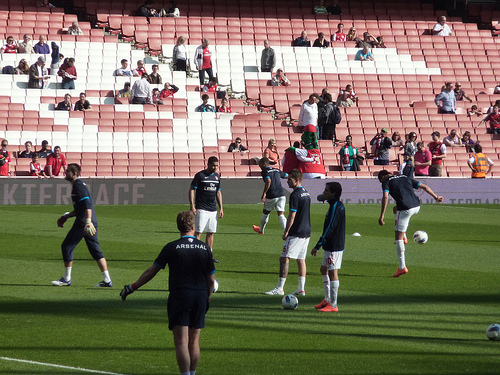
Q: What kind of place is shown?
A: It is a field.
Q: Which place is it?
A: It is a field.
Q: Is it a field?
A: Yes, it is a field.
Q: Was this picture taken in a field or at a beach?
A: It was taken at a field.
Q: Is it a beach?
A: No, it is a field.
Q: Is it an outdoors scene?
A: Yes, it is outdoors.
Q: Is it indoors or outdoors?
A: It is outdoors.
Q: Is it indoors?
A: No, it is outdoors.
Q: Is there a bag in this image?
A: No, there are no bags.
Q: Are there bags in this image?
A: No, there are no bags.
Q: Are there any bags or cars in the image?
A: No, there are no bags or cars.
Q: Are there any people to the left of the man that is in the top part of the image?
A: Yes, there is a person to the left of the man.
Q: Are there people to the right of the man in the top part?
A: No, the person is to the left of the man.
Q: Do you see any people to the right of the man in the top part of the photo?
A: No, the person is to the left of the man.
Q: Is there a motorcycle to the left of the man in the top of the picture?
A: No, there is a person to the left of the man.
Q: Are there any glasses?
A: No, there are no glasses.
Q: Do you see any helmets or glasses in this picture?
A: No, there are no glasses or helmets.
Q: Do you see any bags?
A: No, there are no bags.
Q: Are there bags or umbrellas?
A: No, there are no bags or umbrellas.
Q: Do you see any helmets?
A: No, there are no helmets.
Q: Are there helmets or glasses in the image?
A: No, there are no helmets or glasses.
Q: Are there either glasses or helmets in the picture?
A: No, there are no helmets or glasses.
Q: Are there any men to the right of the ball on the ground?
A: Yes, there is a man to the right of the ball.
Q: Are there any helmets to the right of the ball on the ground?
A: No, there is a man to the right of the ball.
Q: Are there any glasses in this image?
A: No, there are no glasses.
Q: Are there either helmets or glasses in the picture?
A: No, there are no glasses or helmets.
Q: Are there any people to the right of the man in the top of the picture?
A: No, the person is to the left of the man.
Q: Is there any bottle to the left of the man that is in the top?
A: No, there is a person to the left of the man.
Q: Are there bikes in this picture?
A: No, there are no bikes.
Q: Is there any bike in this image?
A: No, there are no bikes.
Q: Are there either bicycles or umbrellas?
A: No, there are no bicycles or umbrellas.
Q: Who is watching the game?
A: The crowd is watching the game.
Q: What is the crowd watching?
A: The crowd is watching the game.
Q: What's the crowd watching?
A: The crowd is watching the game.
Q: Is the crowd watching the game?
A: Yes, the crowd is watching the game.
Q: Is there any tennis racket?
A: No, there are no rackets.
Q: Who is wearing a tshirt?
A: The man is wearing a tshirt.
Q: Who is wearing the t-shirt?
A: The man is wearing a tshirt.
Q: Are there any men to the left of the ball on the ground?
A: Yes, there is a man to the left of the ball.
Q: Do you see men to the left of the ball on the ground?
A: Yes, there is a man to the left of the ball.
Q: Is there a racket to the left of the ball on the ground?
A: No, there is a man to the left of the ball.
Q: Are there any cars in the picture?
A: No, there are no cars.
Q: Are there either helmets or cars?
A: No, there are no cars or helmets.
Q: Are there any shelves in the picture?
A: No, there are no shelves.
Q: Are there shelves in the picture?
A: No, there are no shelves.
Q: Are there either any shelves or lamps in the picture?
A: No, there are no shelves or lamps.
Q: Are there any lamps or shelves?
A: No, there are no shelves or lamps.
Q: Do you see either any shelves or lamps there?
A: No, there are no shelves or lamps.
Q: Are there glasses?
A: No, there are no glasses.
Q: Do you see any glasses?
A: No, there are no glasses.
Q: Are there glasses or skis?
A: No, there are no glasses or skis.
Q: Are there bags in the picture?
A: No, there are no bags.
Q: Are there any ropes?
A: No, there are no ropes.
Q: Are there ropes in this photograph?
A: No, there are no ropes.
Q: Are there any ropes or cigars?
A: No, there are no ropes or cigars.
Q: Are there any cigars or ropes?
A: No, there are no ropes or cigars.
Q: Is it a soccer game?
A: Yes, that is a soccer game.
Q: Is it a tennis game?
A: No, that is a soccer game.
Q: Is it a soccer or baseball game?
A: That is a soccer game.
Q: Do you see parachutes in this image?
A: No, there are no parachutes.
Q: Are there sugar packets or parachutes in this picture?
A: No, there are no parachutes or sugar packets.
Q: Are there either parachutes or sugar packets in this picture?
A: No, there are no parachutes or sugar packets.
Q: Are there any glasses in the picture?
A: No, there are no glasses.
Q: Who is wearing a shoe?
A: The man is wearing a shoe.